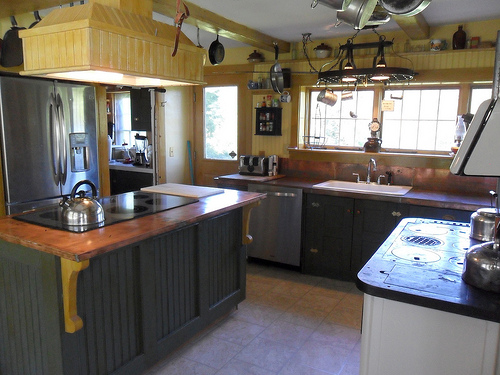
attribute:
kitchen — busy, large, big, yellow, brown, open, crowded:
[23, 26, 488, 327]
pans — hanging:
[176, 11, 299, 98]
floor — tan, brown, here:
[251, 276, 348, 365]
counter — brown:
[413, 175, 467, 220]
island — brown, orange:
[169, 171, 237, 238]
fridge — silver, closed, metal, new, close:
[17, 83, 106, 183]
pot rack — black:
[316, 35, 419, 89]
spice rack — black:
[254, 99, 281, 137]